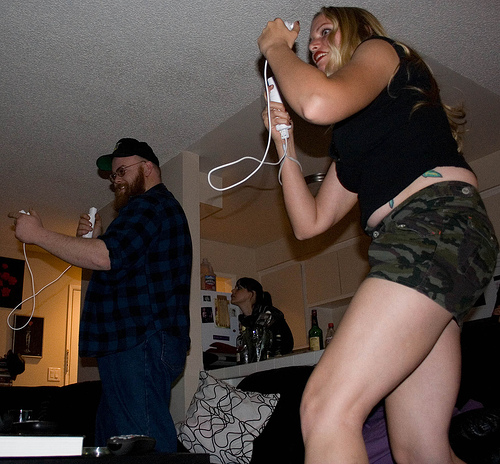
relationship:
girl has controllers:
[230, 0, 500, 464] [241, 12, 335, 127]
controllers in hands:
[241, 12, 335, 127] [235, 13, 340, 64]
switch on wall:
[28, 326, 84, 400] [22, 278, 107, 440]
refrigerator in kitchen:
[208, 283, 230, 350] [226, 262, 391, 380]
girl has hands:
[230, 0, 500, 464] [235, 13, 340, 64]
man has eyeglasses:
[109, 151, 147, 178] [109, 157, 158, 181]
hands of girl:
[235, 13, 340, 64] [230, 0, 500, 464]